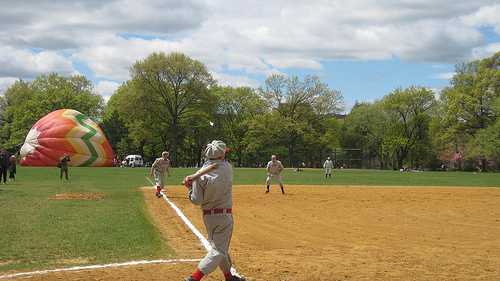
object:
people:
[185, 140, 256, 278]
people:
[258, 154, 293, 202]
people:
[323, 154, 336, 179]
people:
[151, 146, 169, 198]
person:
[254, 141, 294, 179]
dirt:
[394, 253, 424, 267]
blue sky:
[319, 57, 451, 109]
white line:
[147, 177, 240, 279]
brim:
[225, 148, 230, 153]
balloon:
[18, 108, 116, 167]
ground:
[32, 190, 162, 254]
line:
[144, 177, 238, 279]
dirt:
[301, 269, 337, 279]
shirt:
[264, 162, 284, 174]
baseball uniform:
[187, 159, 235, 274]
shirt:
[190, 160, 245, 212]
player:
[153, 130, 293, 277]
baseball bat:
[181, 162, 216, 187]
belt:
[203, 209, 231, 214]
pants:
[197, 212, 233, 275]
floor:
[268, 235, 427, 262]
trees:
[0, 45, 499, 181]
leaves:
[185, 106, 197, 111]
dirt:
[433, 237, 464, 252]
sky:
[11, 6, 413, 74]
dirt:
[464, 263, 498, 278]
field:
[0, 170, 500, 281]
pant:
[154, 170, 165, 190]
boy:
[179, 139, 251, 281]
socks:
[181, 256, 238, 275]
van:
[119, 147, 147, 167]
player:
[178, 138, 248, 279]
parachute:
[12, 105, 126, 165]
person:
[174, 137, 244, 278]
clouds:
[0, 0, 124, 75]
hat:
[204, 139, 230, 158]